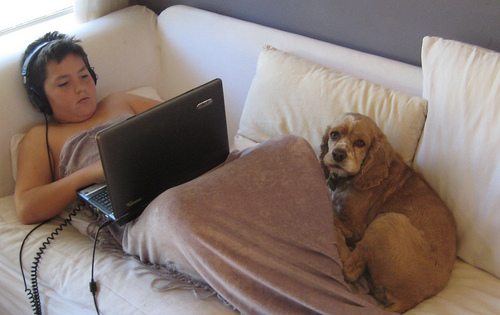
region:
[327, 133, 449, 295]
The dog is laying on the couch.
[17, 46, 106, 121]
The boy has headphone across his ears.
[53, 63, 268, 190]
The boy is using the laptop.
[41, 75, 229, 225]
The boy does not have on a shirt.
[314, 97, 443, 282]
The brown dog is looking at the camera.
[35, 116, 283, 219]
The black laptop is open.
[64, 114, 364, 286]
The boy has a blanket wrapped around his body.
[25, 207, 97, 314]
Cords are hanging from the laptop.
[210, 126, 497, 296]
The brown dog is laying by the boy legs.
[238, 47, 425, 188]
A pillow is on the couch.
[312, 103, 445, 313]
Cocker spaniel mix staring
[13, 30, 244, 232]
Kid with no shirt using computer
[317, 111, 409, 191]
Cocker Spaniel with floppy ears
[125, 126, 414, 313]
Pink sheets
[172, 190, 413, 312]
Wrinkles on pink sheet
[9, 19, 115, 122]
Adolescent boy wearing headphones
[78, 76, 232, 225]
Grey laptop being used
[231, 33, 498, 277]
Two white pillows on couch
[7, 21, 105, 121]
Shaggy brown messy hair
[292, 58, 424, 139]
Wrinkles on white pillow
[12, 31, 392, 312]
a boy is resting on a couch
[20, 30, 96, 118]
the boy has earphones on his head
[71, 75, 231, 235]
an open lap top is on the boy's lap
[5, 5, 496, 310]
the boy and dog is on a white sofa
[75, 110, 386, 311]
a dusty pink blanket is wrapped around the boy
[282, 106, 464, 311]
a brown dog is at the feet of the boy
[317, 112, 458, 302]
the dog is curled up next to the boy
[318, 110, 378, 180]
the dog's face is white and brown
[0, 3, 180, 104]
a window is behind the boy's head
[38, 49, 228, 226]
the boy is writing on the keyboard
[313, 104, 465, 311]
Dog on the couch.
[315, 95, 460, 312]
The dog is blonde.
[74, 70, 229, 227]
the laptop is black.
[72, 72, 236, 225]
the computer is a laptop.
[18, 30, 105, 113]
Boy is wearing headphones.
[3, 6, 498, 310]
The couch is white.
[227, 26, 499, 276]
Pillows on the couch.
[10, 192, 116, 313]
Cords hanging on computer.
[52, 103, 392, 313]
Boy under a blanket.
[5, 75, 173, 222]
The boy is shirtless.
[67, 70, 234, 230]
The computer is black.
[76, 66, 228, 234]
The computer is a laptop.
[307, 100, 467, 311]
Dog laying on a couch.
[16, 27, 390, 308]
Boy laying on the couch.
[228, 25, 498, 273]
The pillow is white.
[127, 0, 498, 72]
The wall is blue.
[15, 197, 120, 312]
The cords are black.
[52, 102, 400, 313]
Boy is under a blanket.